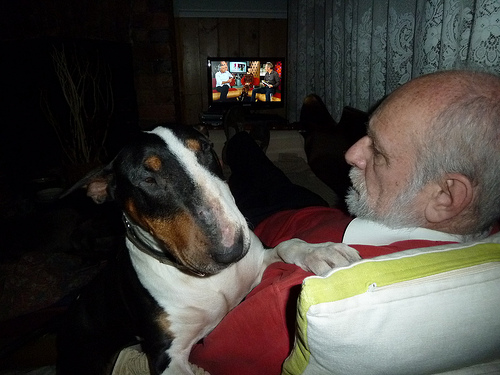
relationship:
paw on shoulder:
[277, 234, 362, 282] [242, 206, 440, 352]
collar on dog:
[119, 212, 197, 278] [82, 117, 370, 374]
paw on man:
[295, 242, 363, 277] [252, 61, 498, 274]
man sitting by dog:
[175, 61, 498, 333] [59, 120, 361, 374]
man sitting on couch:
[175, 61, 498, 333] [251, 261, 496, 367]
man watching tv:
[175, 61, 498, 333] [198, 39, 310, 127]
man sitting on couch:
[175, 61, 498, 333] [245, 254, 498, 364]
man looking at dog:
[175, 61, 498, 333] [85, 97, 375, 373]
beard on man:
[343, 168, 424, 230] [175, 61, 498, 333]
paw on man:
[295, 242, 363, 277] [241, 73, 495, 373]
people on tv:
[213, 65, 278, 87] [193, 30, 295, 132]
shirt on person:
[213, 69, 233, 90] [212, 57, 234, 99]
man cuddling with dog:
[175, 61, 498, 333] [109, 118, 266, 297]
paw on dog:
[295, 242, 363, 277] [59, 120, 361, 374]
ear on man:
[425, 174, 471, 221] [211, 69, 495, 374]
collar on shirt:
[337, 209, 497, 249] [188, 205, 498, 374]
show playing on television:
[212, 54, 285, 104] [201, 52, 291, 122]